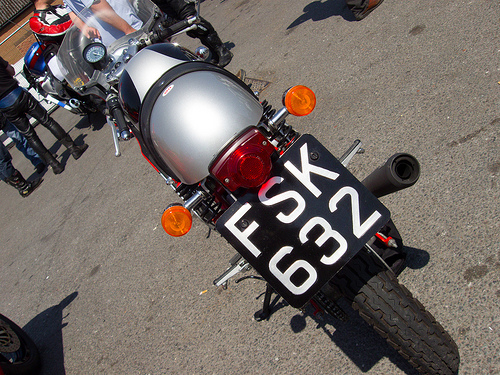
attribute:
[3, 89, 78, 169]
pants — leather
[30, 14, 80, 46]
jacket — red, black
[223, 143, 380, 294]
words — written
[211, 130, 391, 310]
plate — black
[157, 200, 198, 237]
tail light — orange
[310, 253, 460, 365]
tire — black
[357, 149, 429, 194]
exhaust pipe — dark, black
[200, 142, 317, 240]
words — white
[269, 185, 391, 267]
words — white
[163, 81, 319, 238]
taillight — red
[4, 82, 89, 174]
pants — black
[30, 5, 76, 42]
jacket — tight fitting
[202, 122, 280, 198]
rear lamp — behind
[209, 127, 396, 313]
license plate — Black 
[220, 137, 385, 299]
writing — white 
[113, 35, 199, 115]
tank — black, white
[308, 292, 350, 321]
chain — driving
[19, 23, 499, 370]
motorcycle — Silver and blacn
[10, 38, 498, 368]
lot — parking, grey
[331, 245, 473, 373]
tire — black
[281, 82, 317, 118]
light — orange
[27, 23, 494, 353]
floor — gray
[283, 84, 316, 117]
taillight — orange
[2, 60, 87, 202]
riders — standing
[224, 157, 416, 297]
plate — behind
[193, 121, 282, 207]
light — red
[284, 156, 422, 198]
exhauster — black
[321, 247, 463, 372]
wheel — black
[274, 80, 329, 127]
tailight — red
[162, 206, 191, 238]
light — orange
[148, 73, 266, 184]
frame — grey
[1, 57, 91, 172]
person — black